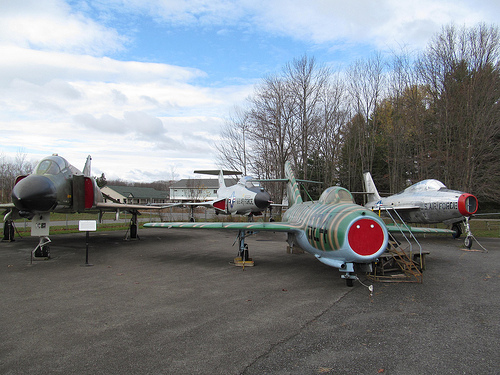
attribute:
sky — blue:
[176, 22, 226, 71]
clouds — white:
[291, 13, 348, 46]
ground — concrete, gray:
[382, 313, 414, 336]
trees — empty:
[320, 117, 421, 146]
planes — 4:
[20, 136, 481, 289]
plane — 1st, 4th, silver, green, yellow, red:
[292, 191, 410, 274]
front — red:
[341, 217, 391, 253]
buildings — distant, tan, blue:
[113, 174, 217, 207]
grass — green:
[485, 230, 493, 240]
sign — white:
[78, 215, 114, 247]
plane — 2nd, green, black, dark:
[12, 154, 110, 207]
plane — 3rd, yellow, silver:
[172, 153, 271, 207]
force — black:
[244, 194, 261, 214]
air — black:
[235, 189, 244, 206]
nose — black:
[10, 185, 51, 210]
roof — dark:
[111, 185, 155, 199]